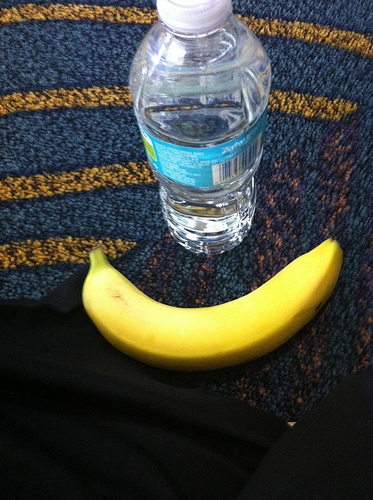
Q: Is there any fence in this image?
A: No, there are no fences.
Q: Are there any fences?
A: No, there are no fences.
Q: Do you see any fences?
A: No, there are no fences.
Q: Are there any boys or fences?
A: No, there are no fences or boys.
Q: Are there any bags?
A: No, there are no bags.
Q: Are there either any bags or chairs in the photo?
A: No, there are no bags or chairs.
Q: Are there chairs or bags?
A: No, there are no bags or chairs.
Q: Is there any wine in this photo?
A: No, there is no wine.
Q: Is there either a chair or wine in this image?
A: No, there are no wine or chairs.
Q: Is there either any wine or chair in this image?
A: No, there are no wine or chairs.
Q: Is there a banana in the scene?
A: Yes, there is a banana.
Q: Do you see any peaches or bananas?
A: Yes, there is a banana.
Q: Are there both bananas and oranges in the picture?
A: No, there is a banana but no oranges.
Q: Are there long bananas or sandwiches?
A: Yes, there is a long banana.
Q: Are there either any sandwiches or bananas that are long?
A: Yes, the banana is long.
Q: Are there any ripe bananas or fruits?
A: Yes, there is a ripe banana.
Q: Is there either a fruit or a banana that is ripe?
A: Yes, the banana is ripe.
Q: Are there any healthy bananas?
A: Yes, there is a healthy banana.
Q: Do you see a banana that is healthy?
A: Yes, there is a banana that is healthy.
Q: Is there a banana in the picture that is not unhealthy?
A: Yes, there is an healthy banana.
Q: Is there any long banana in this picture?
A: Yes, there is a long banana.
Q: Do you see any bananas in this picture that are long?
A: Yes, there is a banana that is long.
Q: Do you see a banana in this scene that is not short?
A: Yes, there is a long banana.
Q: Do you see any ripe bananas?
A: Yes, there is a ripe banana.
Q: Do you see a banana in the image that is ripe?
A: Yes, there is a banana that is ripe.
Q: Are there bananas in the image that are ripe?
A: Yes, there is a banana that is ripe.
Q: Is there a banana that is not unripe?
A: Yes, there is an ripe banana.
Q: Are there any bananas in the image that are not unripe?
A: Yes, there is an ripe banana.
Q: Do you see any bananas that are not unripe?
A: Yes, there is an ripe banana.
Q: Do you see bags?
A: No, there are no bags.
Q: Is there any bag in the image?
A: No, there are no bags.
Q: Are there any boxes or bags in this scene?
A: No, there are no bags or boxes.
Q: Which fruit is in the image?
A: The fruit is a banana.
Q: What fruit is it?
A: The fruit is a banana.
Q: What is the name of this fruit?
A: This is a banana.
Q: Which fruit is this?
A: This is a banana.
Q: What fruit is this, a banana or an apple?
A: This is a banana.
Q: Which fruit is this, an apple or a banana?
A: This is a banana.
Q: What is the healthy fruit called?
A: The fruit is a banana.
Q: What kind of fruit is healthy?
A: The fruit is a banana.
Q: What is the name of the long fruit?
A: The fruit is a banana.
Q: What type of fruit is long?
A: The fruit is a banana.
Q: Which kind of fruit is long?
A: The fruit is a banana.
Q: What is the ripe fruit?
A: The fruit is a banana.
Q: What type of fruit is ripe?
A: The fruit is a banana.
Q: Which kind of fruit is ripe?
A: The fruit is a banana.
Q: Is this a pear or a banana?
A: This is a banana.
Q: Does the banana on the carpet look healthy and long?
A: Yes, the banana is healthy and long.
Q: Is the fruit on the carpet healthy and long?
A: Yes, the banana is healthy and long.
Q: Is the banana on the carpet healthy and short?
A: No, the banana is healthy but long.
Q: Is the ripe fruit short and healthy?
A: No, the banana is healthy but long.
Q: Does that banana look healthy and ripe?
A: Yes, the banana is healthy and ripe.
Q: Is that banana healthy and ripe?
A: Yes, the banana is healthy and ripe.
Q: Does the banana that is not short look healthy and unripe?
A: No, the banana is healthy but ripe.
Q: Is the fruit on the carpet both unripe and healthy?
A: No, the banana is healthy but ripe.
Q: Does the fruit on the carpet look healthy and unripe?
A: No, the banana is healthy but ripe.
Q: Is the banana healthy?
A: Yes, the banana is healthy.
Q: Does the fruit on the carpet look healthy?
A: Yes, the banana is healthy.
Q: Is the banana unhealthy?
A: No, the banana is healthy.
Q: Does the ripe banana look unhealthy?
A: No, the banana is healthy.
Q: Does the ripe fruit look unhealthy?
A: No, the banana is healthy.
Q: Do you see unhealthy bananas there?
A: No, there is a banana but it is healthy.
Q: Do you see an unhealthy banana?
A: No, there is a banana but it is healthy.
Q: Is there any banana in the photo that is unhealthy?
A: No, there is a banana but it is healthy.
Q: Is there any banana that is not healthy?
A: No, there is a banana but it is healthy.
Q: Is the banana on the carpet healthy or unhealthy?
A: The banana is healthy.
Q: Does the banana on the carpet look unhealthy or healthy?
A: The banana is healthy.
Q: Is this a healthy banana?
A: Yes, this is a healthy banana.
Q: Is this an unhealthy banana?
A: No, this is a healthy banana.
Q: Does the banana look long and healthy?
A: Yes, the banana is long and healthy.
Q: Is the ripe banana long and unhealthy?
A: No, the banana is long but healthy.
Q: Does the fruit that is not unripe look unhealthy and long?
A: No, the banana is long but healthy.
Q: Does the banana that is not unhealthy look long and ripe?
A: Yes, the banana is long and ripe.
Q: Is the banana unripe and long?
A: No, the banana is long but ripe.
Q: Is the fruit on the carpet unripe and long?
A: No, the banana is long but ripe.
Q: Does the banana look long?
A: Yes, the banana is long.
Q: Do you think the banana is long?
A: Yes, the banana is long.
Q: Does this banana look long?
A: Yes, the banana is long.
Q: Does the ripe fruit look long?
A: Yes, the banana is long.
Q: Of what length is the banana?
A: The banana is long.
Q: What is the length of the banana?
A: The banana is long.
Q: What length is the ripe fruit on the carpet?
A: The banana is long.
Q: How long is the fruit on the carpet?
A: The banana is long.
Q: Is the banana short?
A: No, the banana is long.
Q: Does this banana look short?
A: No, the banana is long.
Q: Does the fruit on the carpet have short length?
A: No, the banana is long.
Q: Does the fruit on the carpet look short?
A: No, the banana is long.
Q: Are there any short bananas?
A: No, there is a banana but it is long.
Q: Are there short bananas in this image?
A: No, there is a banana but it is long.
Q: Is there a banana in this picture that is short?
A: No, there is a banana but it is long.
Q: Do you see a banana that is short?
A: No, there is a banana but it is long.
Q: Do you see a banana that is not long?
A: No, there is a banana but it is long.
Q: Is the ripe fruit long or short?
A: The banana is long.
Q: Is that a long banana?
A: Yes, that is a long banana.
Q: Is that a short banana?
A: No, that is a long banana.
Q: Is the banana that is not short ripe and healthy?
A: Yes, the banana is ripe and healthy.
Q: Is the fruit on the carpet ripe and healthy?
A: Yes, the banana is ripe and healthy.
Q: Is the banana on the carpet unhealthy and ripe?
A: No, the banana is ripe but healthy.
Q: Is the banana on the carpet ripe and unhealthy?
A: No, the banana is ripe but healthy.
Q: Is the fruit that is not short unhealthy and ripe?
A: No, the banana is ripe but healthy.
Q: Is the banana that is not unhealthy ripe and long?
A: Yes, the banana is ripe and long.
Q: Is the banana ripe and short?
A: No, the banana is ripe but long.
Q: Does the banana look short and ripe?
A: No, the banana is ripe but long.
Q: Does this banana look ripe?
A: Yes, the banana is ripe.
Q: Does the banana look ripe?
A: Yes, the banana is ripe.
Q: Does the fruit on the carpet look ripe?
A: Yes, the banana is ripe.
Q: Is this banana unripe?
A: No, the banana is ripe.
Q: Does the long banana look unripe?
A: No, the banana is ripe.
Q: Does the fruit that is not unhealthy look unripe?
A: No, the banana is ripe.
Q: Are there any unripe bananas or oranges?
A: No, there is a banana but it is ripe.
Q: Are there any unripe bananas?
A: No, there is a banana but it is ripe.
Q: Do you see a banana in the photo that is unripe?
A: No, there is a banana but it is ripe.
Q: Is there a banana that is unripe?
A: No, there is a banana but it is ripe.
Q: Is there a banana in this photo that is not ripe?
A: No, there is a banana but it is ripe.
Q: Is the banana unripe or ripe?
A: The banana is ripe.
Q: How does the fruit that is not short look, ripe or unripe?
A: The banana is ripe.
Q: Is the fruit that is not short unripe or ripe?
A: The banana is ripe.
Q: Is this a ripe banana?
A: Yes, this is a ripe banana.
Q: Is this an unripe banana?
A: No, this is a ripe banana.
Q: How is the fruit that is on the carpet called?
A: The fruit is a banana.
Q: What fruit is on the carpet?
A: The fruit is a banana.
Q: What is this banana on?
A: The banana is on the carpet.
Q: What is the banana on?
A: The banana is on the carpet.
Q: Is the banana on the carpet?
A: Yes, the banana is on the carpet.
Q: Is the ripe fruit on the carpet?
A: Yes, the banana is on the carpet.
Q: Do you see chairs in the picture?
A: No, there are no chairs.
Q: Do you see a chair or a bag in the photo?
A: No, there are no chairs or bags.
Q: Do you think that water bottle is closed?
A: Yes, the water bottle is closed.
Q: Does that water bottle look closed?
A: Yes, the water bottle is closed.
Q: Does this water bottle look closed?
A: Yes, the water bottle is closed.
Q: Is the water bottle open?
A: No, the water bottle is closed.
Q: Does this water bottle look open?
A: No, the water bottle is closed.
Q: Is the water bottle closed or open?
A: The water bottle is closed.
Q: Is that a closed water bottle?
A: Yes, that is a closed water bottle.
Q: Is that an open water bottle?
A: No, that is a closed water bottle.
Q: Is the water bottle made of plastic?
A: Yes, the water bottle is made of plastic.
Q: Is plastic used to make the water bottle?
A: Yes, the water bottle is made of plastic.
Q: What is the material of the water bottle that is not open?
A: The water bottle is made of plastic.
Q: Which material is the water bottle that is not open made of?
A: The water bottle is made of plastic.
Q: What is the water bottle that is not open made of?
A: The water bottle is made of plastic.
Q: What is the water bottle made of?
A: The water bottle is made of plastic.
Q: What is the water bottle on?
A: The water bottle is on the carpet.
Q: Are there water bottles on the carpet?
A: Yes, there is a water bottle on the carpet.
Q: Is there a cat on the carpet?
A: No, there is a water bottle on the carpet.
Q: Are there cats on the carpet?
A: No, there is a water bottle on the carpet.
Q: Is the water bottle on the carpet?
A: Yes, the water bottle is on the carpet.